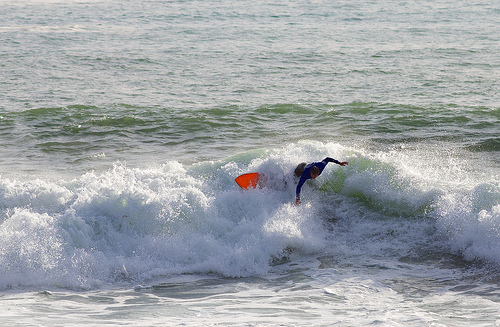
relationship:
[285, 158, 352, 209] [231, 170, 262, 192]
person riding surfboard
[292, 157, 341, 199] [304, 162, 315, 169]
wetsuit has logo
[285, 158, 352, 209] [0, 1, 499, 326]
person in ocean